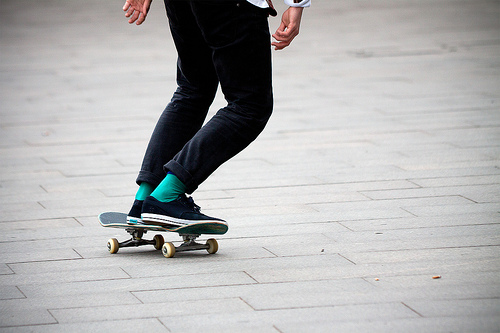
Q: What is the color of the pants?
A: Ebony black.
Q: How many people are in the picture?
A: One.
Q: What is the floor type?
A: Concrete.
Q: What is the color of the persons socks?
A: Green.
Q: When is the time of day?
A: Daytime.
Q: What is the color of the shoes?
A: Black.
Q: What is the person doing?
A: Skateboarding.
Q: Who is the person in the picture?
A: Male.